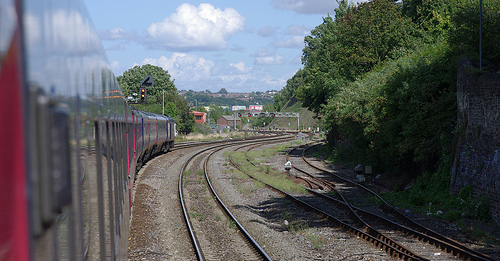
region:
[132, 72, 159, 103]
small traffic light over train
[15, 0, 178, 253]
row of grey train cars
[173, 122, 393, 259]
train tracks curving to the right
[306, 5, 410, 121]
leafy green tree on embankment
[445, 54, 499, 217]
rock embankment along tracks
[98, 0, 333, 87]
white clouds in a blue sky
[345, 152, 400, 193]
trash scattered along tracks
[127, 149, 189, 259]
grey gravel alongside train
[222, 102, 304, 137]
lights on metal array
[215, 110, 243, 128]
small brown building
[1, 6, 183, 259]
the train in perspective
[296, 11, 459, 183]
leafy green shrubs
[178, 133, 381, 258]
several train rails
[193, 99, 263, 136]
several houses in the distance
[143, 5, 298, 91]
a great white cloud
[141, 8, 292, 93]
a beautiful sunny day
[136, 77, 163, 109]
the train traffic light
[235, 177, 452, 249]
the shadow of the trees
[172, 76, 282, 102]
big mountain in the distance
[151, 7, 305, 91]
clouds of different sizes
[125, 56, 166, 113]
two lights are lit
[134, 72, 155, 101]
lights are red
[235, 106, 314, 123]
lights that go across the tracks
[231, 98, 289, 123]
four lights are red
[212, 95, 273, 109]
billboards behind the train lights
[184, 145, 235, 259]
weeds between the tracks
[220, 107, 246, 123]
building behind the train lights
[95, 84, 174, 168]
red in the doorways of the train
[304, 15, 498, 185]
trees on the wall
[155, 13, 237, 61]
white puffy cloud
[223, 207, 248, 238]
edge of a rail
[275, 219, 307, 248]
part of a ground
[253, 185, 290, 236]
part of a shade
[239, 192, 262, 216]
part of a shade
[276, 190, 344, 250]
part of a shade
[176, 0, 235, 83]
part of a cloud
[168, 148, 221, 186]
The train tracks curve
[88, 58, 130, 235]
Train on the tracks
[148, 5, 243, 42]
White cloud in the sky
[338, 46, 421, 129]
Green shrubbery by the tracks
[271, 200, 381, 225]
Shadow on the tracks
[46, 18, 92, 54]
Cloud reflection on the train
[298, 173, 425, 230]
The train tracks change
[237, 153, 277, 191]
Grass on the train tracks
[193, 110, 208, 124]
Red building by the tracks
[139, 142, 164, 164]
Wheels of the train